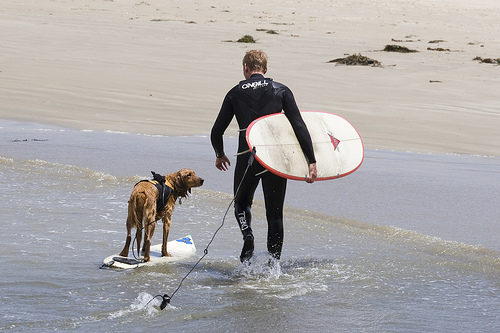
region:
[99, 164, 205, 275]
A dog is on a surfboard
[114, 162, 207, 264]
The dog is brown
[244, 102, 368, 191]
Surfboard under man's arm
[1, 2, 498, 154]
Sand on the beach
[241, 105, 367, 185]
Surfboard is white and red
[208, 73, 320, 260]
A black wet suit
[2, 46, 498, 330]
Dog and man standing in the water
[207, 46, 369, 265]
Surfer is holding a surfboard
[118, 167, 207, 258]
Dog is wearing a life vest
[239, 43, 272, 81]
Blonde hair on man's head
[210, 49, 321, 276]
surfboarder on seashore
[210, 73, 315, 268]
black wetsuit of surfboarder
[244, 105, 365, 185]
white surfboard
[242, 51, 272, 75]
blonde short hair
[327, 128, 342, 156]
red symbol on white surfboard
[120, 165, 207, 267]
wet dog on seashore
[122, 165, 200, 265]
dog on seashort on white surfboard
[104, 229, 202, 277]
lnight blue and white surfboard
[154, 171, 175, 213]
little black wetsuit of dog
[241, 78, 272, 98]
white symbol on back of wetsuit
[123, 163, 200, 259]
the dog is brown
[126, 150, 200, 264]
the dog is wet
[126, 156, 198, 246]
the dog is on the surfboard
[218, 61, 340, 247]
the surfer is in a black swimsuit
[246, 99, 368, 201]
the surfboard is white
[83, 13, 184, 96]
the beach sand is brown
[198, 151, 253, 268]
a cable is attcahed to the surfboard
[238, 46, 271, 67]
the hair is brown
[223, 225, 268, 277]
one leg is up in the air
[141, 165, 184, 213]
life jacket is around the dog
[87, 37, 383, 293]
man and his dog coming in from surfing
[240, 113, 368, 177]
white surfboard with a red edge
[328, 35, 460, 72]
clumps of seaweed on the beach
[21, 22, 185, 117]
very smooth tan sand of the beach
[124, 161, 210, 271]
wet brown dog looking at his owner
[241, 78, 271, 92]
white logo on the back side of the wetsuit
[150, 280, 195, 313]
black end of the anchor for the surfboard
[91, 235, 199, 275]
small white surfboard the dog rides on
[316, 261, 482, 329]
shallow clear water at the edge of the beach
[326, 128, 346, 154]
red triangle logo on the surfboard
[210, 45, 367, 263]
Man holding a surfboard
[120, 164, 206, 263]
A brown furry dog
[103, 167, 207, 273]
Dog on a surfboard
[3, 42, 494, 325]
Dog and man in the water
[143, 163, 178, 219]
A black life vest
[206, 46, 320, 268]
Man wearing black wetsuit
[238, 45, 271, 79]
Man has blonde hair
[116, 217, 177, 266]
Four legs of a dog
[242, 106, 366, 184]
A white surfboard with red border